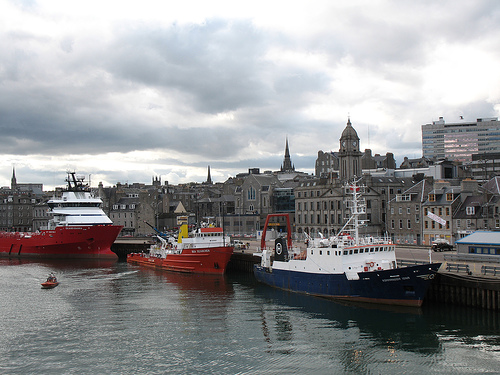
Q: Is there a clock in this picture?
A: No, there are no clocks.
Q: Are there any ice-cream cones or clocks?
A: No, there are no clocks or ice-cream cones.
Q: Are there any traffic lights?
A: No, there are no traffic lights.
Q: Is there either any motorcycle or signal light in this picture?
A: No, there are no traffic lights or motorcycles.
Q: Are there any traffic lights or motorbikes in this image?
A: No, there are no traffic lights or motorbikes.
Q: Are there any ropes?
A: No, there are no ropes.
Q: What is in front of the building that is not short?
A: The boats are in front of the building.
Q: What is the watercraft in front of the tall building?
A: The watercraft is boats.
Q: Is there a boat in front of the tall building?
A: Yes, there are boats in front of the building.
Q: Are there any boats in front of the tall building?
A: Yes, there are boats in front of the building.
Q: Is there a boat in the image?
A: Yes, there is a boat.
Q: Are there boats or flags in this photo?
A: Yes, there is a boat.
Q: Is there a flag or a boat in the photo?
A: Yes, there is a boat.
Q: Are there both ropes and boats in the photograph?
A: No, there is a boat but no ropes.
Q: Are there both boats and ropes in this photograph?
A: No, there is a boat but no ropes.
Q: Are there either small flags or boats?
A: Yes, there is a small boat.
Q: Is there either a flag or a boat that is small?
A: Yes, the boat is small.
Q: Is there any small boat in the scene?
A: Yes, there is a small boat.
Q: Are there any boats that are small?
A: Yes, there is a boat that is small.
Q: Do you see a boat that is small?
A: Yes, there is a boat that is small.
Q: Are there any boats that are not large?
A: Yes, there is a small boat.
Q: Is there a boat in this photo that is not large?
A: Yes, there is a small boat.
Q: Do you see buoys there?
A: No, there are no buoys.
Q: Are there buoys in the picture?
A: No, there are no buoys.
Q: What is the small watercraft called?
A: The watercraft is a boat.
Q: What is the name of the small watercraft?
A: The watercraft is a boat.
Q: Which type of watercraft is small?
A: The watercraft is a boat.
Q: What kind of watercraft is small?
A: The watercraft is a boat.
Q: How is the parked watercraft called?
A: The watercraft is a boat.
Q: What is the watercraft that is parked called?
A: The watercraft is a boat.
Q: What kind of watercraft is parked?
A: The watercraft is a boat.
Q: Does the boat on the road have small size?
A: Yes, the boat is small.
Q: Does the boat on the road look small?
A: Yes, the boat is small.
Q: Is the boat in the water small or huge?
A: The boat is small.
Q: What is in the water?
A: The boat is in the water.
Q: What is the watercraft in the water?
A: The watercraft is a boat.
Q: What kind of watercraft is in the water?
A: The watercraft is a boat.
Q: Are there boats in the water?
A: Yes, there is a boat in the water.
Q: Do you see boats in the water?
A: Yes, there is a boat in the water.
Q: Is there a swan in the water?
A: No, there is a boat in the water.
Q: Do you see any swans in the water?
A: No, there is a boat in the water.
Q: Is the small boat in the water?
A: Yes, the boat is in the water.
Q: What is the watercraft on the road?
A: The watercraft is a boat.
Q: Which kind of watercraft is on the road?
A: The watercraft is a boat.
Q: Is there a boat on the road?
A: Yes, there is a boat on the road.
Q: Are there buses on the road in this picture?
A: No, there is a boat on the road.